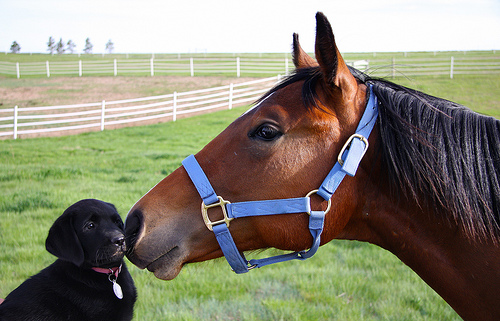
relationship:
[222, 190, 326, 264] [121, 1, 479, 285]
bridle on horse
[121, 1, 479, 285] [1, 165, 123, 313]
horse touching dog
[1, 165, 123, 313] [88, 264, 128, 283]
dog has collar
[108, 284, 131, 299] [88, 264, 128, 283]
tag on collar